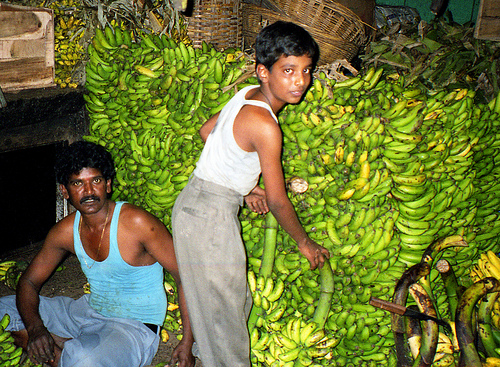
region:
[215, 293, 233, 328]
part of a trouser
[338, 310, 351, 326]
part of a banana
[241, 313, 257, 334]
edge of a trouser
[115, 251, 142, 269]
edge of a vest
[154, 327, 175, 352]
part of a floor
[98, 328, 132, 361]
part of a jeans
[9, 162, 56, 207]
part of a hollow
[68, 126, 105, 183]
part of some hairs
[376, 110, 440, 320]
the bananas are green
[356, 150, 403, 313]
the bananas are green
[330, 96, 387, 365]
the bananas are green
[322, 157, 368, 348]
the bananas are green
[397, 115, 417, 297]
the bananas are green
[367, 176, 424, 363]
the bananas are green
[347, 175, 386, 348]
the bananas are green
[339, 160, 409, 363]
the bananas are green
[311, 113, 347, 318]
the bananas are green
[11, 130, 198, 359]
a man sitting down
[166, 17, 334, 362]
a young boy standing up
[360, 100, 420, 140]
a bunch of green bananas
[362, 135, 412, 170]
a bunch of green bananas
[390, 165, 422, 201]
a bunch of green bananas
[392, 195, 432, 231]
a bunch of green bananas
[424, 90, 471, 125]
a bunch of green bananas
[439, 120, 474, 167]
a bunch of green bananas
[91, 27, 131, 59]
a bunch of green bananas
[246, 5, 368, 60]
a stack of wicker baskets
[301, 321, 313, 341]
part of a banana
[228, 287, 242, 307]
par of a trouser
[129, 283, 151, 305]
part of a vest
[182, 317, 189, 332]
edge of an arm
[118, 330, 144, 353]
part of a jeans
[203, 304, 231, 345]
part of a trouser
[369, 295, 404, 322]
part of a handle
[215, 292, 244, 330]
part of a trouser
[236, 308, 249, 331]
edge of a long